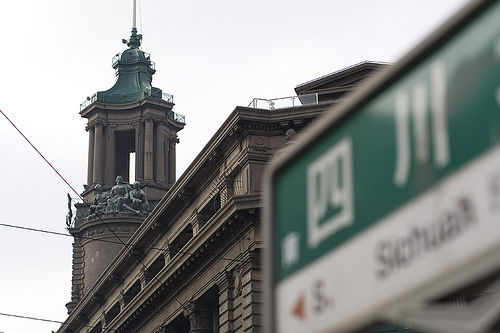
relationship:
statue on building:
[84, 172, 155, 218] [67, 0, 186, 312]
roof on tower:
[77, 27, 177, 112] [66, 0, 186, 317]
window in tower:
[113, 127, 140, 184] [66, 0, 186, 317]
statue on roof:
[120, 27, 143, 47] [78, 2, 175, 112]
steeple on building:
[133, 0, 138, 31] [67, 0, 186, 312]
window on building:
[89, 319, 101, 330] [57, 59, 394, 330]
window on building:
[123, 278, 143, 310] [57, 59, 394, 330]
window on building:
[145, 250, 165, 282] [57, 59, 394, 330]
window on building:
[168, 222, 194, 264] [57, 59, 394, 330]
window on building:
[113, 127, 140, 184] [57, 59, 394, 330]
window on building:
[189, 285, 225, 330] [32, 5, 394, 330]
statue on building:
[84, 172, 155, 218] [34, 7, 436, 331]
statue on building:
[84, 172, 155, 218] [73, 59, 204, 253]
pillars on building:
[80, 131, 173, 178] [36, 11, 471, 321]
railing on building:
[242, 91, 346, 109] [50, 78, 484, 328]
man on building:
[81, 174, 161, 227] [50, 78, 484, 328]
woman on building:
[78, 174, 152, 213] [50, 78, 484, 328]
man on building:
[91, 161, 140, 205] [36, 11, 471, 321]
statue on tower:
[84, 172, 155, 218] [45, 8, 180, 292]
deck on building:
[59, 175, 131, 238] [1, 10, 483, 298]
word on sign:
[358, 188, 472, 283] [260, 1, 498, 331]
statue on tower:
[84, 172, 155, 218] [73, 16, 222, 275]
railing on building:
[230, 70, 347, 138] [26, 44, 340, 319]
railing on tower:
[77, 90, 207, 131] [62, 32, 191, 272]